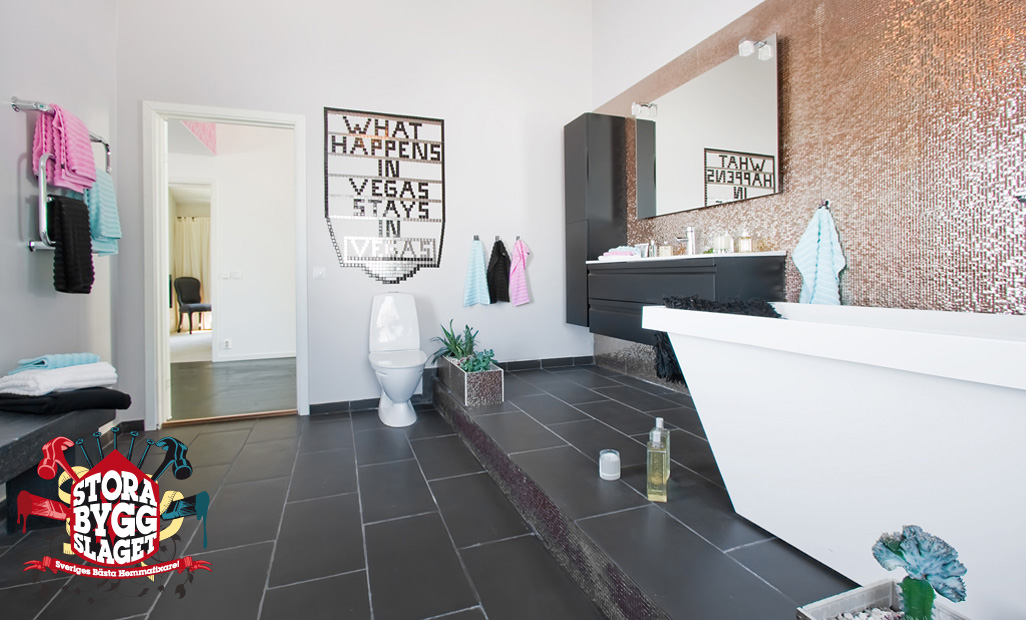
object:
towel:
[14, 98, 114, 208]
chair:
[160, 249, 252, 349]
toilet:
[354, 264, 442, 437]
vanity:
[567, 216, 803, 369]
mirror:
[617, 27, 804, 226]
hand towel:
[462, 229, 491, 317]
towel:
[27, 192, 118, 303]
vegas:
[339, 175, 443, 201]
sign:
[308, 102, 460, 284]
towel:
[776, 194, 860, 307]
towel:
[0, 356, 123, 399]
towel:
[0, 377, 134, 425]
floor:
[5, 349, 1026, 617]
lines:
[244, 407, 313, 617]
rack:
[6, 91, 137, 276]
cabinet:
[530, 110, 792, 375]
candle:
[593, 445, 630, 487]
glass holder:
[593, 443, 628, 483]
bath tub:
[626, 273, 1024, 618]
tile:
[721, 528, 867, 614]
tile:
[639, 483, 789, 565]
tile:
[560, 500, 807, 618]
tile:
[502, 442, 665, 529]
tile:
[466, 397, 576, 463]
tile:
[451, 515, 616, 619]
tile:
[403, 427, 493, 484]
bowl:
[361, 344, 435, 404]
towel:
[504, 231, 536, 316]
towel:
[474, 237, 516, 304]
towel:
[456, 233, 497, 309]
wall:
[0, 0, 1026, 444]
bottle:
[644, 411, 675, 483]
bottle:
[637, 425, 675, 506]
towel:
[78, 164, 131, 264]